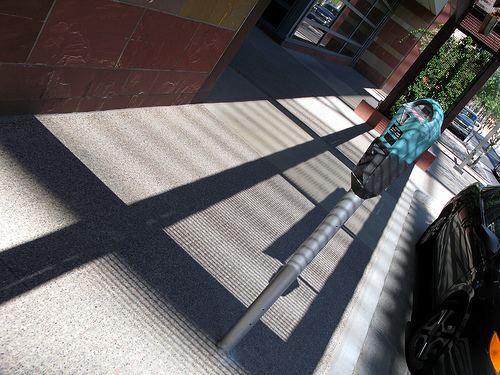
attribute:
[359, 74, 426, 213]
meter — blue, black, parking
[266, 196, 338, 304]
pole — metal, gray, supporting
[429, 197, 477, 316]
car — shiny, next, parked, blue, captured, infront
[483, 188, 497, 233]
window — glass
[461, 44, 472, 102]
column — support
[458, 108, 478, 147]
truck — parked, blue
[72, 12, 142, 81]
wall — here, brown, stone, tile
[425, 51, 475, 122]
tree — beyond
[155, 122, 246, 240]
sidewalk — paved, gray, concrete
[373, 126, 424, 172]
stickers — black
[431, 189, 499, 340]
vehicle — black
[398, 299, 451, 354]
tire — black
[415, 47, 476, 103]
plant — house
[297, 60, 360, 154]
floor — white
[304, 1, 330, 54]
partition — glass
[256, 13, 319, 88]
entrance — here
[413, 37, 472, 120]
plants — green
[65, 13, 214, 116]
bricks — red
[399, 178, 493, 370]
vehicle — black